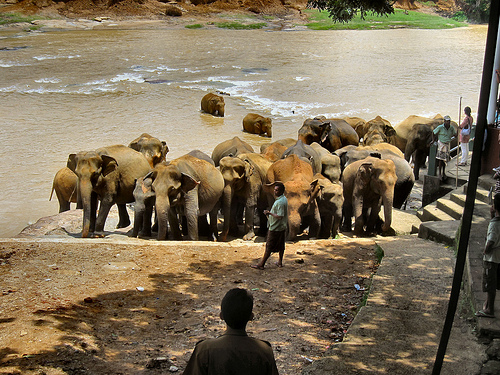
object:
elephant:
[129, 129, 170, 167]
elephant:
[47, 166, 77, 212]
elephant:
[129, 155, 224, 239]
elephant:
[216, 150, 277, 237]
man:
[480, 197, 497, 242]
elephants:
[113, 120, 419, 220]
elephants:
[195, 84, 276, 140]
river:
[4, 29, 436, 147]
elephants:
[201, 92, 280, 140]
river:
[5, 26, 472, 274]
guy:
[258, 181, 290, 272]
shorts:
[267, 230, 284, 254]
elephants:
[44, 86, 481, 226]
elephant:
[63, 149, 149, 240]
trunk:
[76, 175, 93, 236]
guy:
[248, 181, 289, 271]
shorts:
[263, 225, 286, 252]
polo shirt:
[266, 192, 289, 232]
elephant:
[65, 143, 154, 238]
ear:
[65, 152, 77, 172]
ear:
[98, 151, 118, 186]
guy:
[430, 114, 459, 179]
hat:
[441, 113, 451, 123]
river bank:
[1, 209, 471, 371]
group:
[45, 89, 459, 241]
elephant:
[141, 153, 225, 241]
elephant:
[215, 148, 272, 241]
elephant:
[263, 152, 323, 245]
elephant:
[340, 150, 400, 238]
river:
[0, 24, 484, 234]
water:
[0, 22, 482, 234]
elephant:
[199, 90, 226, 117]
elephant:
[241, 111, 272, 137]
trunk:
[218, 107, 225, 117]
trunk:
[265, 130, 272, 138]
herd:
[47, 89, 460, 240]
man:
[248, 180, 290, 271]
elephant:
[261, 150, 323, 237]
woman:
[454, 104, 474, 167]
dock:
[439, 146, 474, 186]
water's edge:
[1, 207, 423, 255]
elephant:
[339, 154, 399, 234]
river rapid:
[1, 52, 370, 120]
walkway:
[310, 201, 484, 372]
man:
[432, 112, 460, 178]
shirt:
[430, 121, 459, 143]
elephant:
[265, 151, 324, 239]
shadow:
[2, 232, 480, 372]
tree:
[304, 0, 396, 23]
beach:
[1, 240, 381, 372]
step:
[419, 201, 457, 224]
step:
[435, 196, 465, 220]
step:
[450, 190, 485, 210]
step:
[463, 182, 484, 202]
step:
[478, 173, 485, 183]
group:
[47, 110, 459, 242]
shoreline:
[1, 205, 484, 373]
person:
[430, 115, 460, 177]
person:
[401, 122, 433, 180]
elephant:
[219, 150, 276, 245]